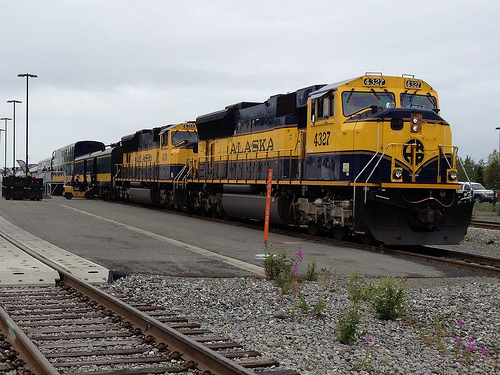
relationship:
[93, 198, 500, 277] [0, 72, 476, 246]
train track under train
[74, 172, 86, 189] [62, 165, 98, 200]
man on forklift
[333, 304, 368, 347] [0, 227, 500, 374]
weed growing through gravel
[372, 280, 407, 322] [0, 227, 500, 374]
weed growing through gravel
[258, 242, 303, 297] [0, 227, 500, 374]
weed growing through gravel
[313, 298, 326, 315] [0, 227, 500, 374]
weed growing through gravel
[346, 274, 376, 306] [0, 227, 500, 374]
weed growing through gravel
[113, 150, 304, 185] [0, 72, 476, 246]
railing on side of train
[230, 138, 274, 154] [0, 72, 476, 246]
alaska on train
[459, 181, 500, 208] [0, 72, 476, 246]
parking lot behind train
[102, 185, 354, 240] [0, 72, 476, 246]
gears on train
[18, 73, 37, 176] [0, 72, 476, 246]
light pole next to train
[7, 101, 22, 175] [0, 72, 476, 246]
light pole next to train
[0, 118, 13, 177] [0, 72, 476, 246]
light pole next to train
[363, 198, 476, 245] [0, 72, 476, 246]
bumper on train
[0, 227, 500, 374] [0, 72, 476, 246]
gravel around train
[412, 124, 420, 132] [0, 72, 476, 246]
center headlight on train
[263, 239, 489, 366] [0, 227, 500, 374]
weeds are growing in gravel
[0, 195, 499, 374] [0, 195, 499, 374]
tracks on ground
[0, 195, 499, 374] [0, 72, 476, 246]
tracks near train